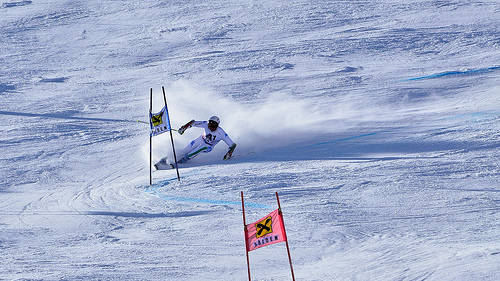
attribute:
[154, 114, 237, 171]
person — skiing, bending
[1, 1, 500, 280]
snow — white, splashing, blowing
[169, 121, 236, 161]
snow gear — white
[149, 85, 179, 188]
sign — white, pink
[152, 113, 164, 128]
icon — yellow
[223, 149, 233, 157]
hand — bent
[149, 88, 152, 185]
stick — thin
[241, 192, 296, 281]
sign — pink, red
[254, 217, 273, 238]
icon — yellow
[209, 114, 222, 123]
helmet — white